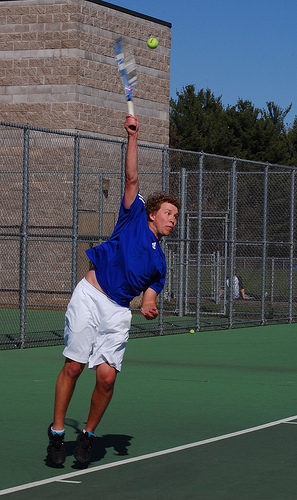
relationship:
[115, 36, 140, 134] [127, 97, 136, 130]
racket has handle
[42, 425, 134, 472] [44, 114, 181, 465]
shadow of man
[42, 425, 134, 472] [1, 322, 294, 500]
shadow cast on court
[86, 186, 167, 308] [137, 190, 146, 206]
shirt has stripes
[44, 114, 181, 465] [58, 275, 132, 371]
man wearing shorts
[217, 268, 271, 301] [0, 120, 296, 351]
man sitting behind fence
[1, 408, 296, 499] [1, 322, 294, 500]
line on top of court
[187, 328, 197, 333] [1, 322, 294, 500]
tennis ball on top of court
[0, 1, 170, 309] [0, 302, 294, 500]
building behind court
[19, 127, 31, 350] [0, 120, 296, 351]
pole supporting fence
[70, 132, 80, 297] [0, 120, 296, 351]
pole supporting fence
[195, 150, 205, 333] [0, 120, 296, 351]
pole supporting fence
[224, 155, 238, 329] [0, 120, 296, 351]
pole supporting fence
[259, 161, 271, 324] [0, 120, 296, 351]
pole supporting fence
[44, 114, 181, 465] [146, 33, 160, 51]
man hitting tennis ball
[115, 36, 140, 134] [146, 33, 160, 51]
racket and tennis ball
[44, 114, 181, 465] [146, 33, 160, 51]
man jumping to hit tennis ball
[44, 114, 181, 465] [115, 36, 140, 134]
man holding racket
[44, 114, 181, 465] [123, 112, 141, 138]
man has right hand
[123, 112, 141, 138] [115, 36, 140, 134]
right hand holding racket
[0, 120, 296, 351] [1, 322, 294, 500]
fence around court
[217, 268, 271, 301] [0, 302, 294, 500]
man sitting behind court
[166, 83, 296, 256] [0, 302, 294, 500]
trees behind court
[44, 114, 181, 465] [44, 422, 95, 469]
man wearing shoes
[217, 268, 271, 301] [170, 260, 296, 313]
man sitting on ground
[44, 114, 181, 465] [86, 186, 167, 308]
man wearing shirt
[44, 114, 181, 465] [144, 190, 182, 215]
man has hair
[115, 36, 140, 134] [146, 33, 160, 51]
racket hitting tennis ball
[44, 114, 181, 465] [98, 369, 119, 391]
man has knee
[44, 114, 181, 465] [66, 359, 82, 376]
man has knee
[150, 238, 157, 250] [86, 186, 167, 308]
logo on front of shirt